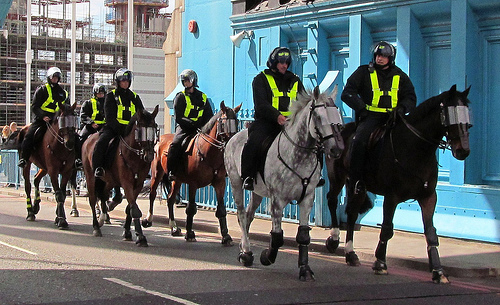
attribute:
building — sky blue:
[182, 2, 498, 247]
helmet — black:
[370, 38, 396, 68]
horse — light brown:
[155, 135, 230, 217]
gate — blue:
[3, 149, 68, 204]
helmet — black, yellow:
[265, 39, 300, 82]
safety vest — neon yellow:
[358, 67, 410, 119]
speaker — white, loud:
[226, 25, 256, 50]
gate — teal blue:
[3, 94, 352, 230]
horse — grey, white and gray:
[222, 82, 349, 284]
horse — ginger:
[148, 97, 242, 246]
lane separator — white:
[0, 241, 200, 302]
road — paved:
[0, 188, 496, 302]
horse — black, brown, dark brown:
[331, 83, 474, 288]